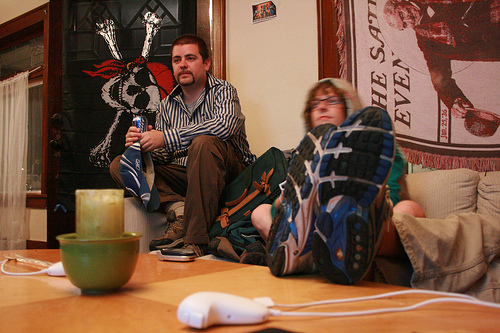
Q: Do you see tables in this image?
A: Yes, there is a table.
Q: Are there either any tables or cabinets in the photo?
A: Yes, there is a table.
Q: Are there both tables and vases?
A: No, there is a table but no vases.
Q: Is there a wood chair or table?
A: Yes, there is a wood table.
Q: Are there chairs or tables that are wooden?
A: Yes, the table is wooden.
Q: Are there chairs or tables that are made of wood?
A: Yes, the table is made of wood.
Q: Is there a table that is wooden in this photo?
A: Yes, there is a wood table.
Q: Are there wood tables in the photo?
A: Yes, there is a wood table.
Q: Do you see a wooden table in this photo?
A: Yes, there is a wood table.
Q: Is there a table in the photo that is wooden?
A: Yes, there is a table that is wooden.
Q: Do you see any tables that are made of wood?
A: Yes, there is a table that is made of wood.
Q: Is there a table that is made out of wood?
A: Yes, there is a table that is made of wood.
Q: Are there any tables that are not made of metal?
A: Yes, there is a table that is made of wood.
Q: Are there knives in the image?
A: No, there are no knives.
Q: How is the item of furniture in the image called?
A: The piece of furniture is a table.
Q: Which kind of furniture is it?
A: The piece of furniture is a table.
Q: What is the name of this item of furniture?
A: This is a table.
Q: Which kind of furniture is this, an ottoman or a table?
A: This is a table.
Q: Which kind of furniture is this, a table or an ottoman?
A: This is a table.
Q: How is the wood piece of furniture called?
A: The piece of furniture is a table.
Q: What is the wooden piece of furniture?
A: The piece of furniture is a table.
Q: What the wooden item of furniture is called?
A: The piece of furniture is a table.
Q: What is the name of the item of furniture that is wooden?
A: The piece of furniture is a table.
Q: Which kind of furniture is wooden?
A: The furniture is a table.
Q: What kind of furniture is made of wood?
A: The furniture is a table.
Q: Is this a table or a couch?
A: This is a table.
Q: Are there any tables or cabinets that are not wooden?
A: No, there is a table but it is wooden.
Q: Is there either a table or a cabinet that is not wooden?
A: No, there is a table but it is wooden.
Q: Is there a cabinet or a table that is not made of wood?
A: No, there is a table but it is made of wood.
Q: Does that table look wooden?
A: Yes, the table is wooden.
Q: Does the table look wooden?
A: Yes, the table is wooden.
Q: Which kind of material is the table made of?
A: The table is made of wood.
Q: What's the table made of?
A: The table is made of wood.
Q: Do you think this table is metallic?
A: No, the table is wooden.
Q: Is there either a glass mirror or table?
A: No, there is a table but it is wooden.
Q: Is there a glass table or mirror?
A: No, there is a table but it is wooden.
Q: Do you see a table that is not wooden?
A: No, there is a table but it is wooden.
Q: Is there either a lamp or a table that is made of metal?
A: No, there is a table but it is made of wood.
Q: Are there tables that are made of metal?
A: No, there is a table but it is made of wood.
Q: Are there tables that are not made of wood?
A: No, there is a table but it is made of wood.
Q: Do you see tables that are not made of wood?
A: No, there is a table but it is made of wood.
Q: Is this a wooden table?
A: Yes, this is a wooden table.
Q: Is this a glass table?
A: No, this is a wooden table.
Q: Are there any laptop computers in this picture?
A: No, there are no laptop computers.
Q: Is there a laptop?
A: No, there are no laptops.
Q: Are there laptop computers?
A: No, there are no laptop computers.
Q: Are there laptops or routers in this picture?
A: No, there are no laptops or routers.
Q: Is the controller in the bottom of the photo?
A: Yes, the controller is in the bottom of the image.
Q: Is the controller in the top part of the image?
A: No, the controller is in the bottom of the image.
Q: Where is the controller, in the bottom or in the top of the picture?
A: The controller is in the bottom of the image.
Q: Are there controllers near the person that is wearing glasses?
A: Yes, there is a controller near the person.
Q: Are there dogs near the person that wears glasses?
A: No, there is a controller near the person.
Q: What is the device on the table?
A: The device is a controller.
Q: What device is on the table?
A: The device is a controller.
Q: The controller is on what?
A: The controller is on the table.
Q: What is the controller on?
A: The controller is on the table.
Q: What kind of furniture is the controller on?
A: The controller is on the table.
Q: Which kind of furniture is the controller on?
A: The controller is on the table.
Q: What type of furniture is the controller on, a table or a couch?
A: The controller is on a table.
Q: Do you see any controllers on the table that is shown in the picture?
A: Yes, there is a controller on the table.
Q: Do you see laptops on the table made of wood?
A: No, there is a controller on the table.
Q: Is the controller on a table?
A: Yes, the controller is on a table.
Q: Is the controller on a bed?
A: No, the controller is on a table.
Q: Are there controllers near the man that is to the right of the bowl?
A: Yes, there is a controller near the man.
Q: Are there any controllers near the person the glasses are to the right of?
A: Yes, there is a controller near the man.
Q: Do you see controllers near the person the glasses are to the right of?
A: Yes, there is a controller near the man.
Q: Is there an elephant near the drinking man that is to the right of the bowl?
A: No, there is a controller near the man.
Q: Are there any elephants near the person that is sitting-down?
A: No, there is a controller near the man.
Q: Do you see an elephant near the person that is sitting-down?
A: No, there is a controller near the man.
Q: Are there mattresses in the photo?
A: No, there are no mattresses.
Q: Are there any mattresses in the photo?
A: No, there are no mattresses.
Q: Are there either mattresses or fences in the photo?
A: No, there are no mattresses or fences.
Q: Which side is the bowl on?
A: The bowl is on the left of the image.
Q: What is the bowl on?
A: The bowl is on the table.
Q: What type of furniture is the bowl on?
A: The bowl is on the table.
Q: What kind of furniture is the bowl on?
A: The bowl is on the table.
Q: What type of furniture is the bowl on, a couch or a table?
A: The bowl is on a table.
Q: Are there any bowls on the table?
A: Yes, there is a bowl on the table.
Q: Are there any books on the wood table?
A: No, there is a bowl on the table.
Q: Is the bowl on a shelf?
A: No, the bowl is on the table.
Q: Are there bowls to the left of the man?
A: Yes, there is a bowl to the left of the man.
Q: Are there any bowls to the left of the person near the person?
A: Yes, there is a bowl to the left of the man.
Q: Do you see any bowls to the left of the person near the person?
A: Yes, there is a bowl to the left of the man.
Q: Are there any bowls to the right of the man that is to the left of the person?
A: No, the bowl is to the left of the man.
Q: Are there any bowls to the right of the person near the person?
A: No, the bowl is to the left of the man.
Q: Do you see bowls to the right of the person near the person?
A: No, the bowl is to the left of the man.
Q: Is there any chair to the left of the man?
A: No, there is a bowl to the left of the man.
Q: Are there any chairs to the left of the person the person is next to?
A: No, there is a bowl to the left of the man.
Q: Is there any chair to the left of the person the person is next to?
A: No, there is a bowl to the left of the man.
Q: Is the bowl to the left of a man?
A: Yes, the bowl is to the left of a man.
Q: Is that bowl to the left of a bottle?
A: No, the bowl is to the left of a man.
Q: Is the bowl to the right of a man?
A: No, the bowl is to the left of a man.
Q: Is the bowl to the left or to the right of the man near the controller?
A: The bowl is to the left of the man.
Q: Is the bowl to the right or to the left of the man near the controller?
A: The bowl is to the left of the man.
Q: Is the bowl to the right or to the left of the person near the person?
A: The bowl is to the left of the man.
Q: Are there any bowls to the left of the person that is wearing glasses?
A: Yes, there is a bowl to the left of the person.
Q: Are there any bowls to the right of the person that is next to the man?
A: No, the bowl is to the left of the person.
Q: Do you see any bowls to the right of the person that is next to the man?
A: No, the bowl is to the left of the person.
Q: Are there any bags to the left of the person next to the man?
A: No, there is a bowl to the left of the person.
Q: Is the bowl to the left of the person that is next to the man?
A: Yes, the bowl is to the left of the person.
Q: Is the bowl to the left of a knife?
A: No, the bowl is to the left of the person.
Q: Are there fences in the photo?
A: No, there are no fences.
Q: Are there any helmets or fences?
A: No, there are no fences or helmets.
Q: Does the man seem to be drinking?
A: Yes, the man is drinking.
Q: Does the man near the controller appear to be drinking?
A: Yes, the man is drinking.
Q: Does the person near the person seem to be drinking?
A: Yes, the man is drinking.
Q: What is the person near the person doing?
A: The man is drinking.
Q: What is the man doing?
A: The man is drinking.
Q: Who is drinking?
A: The man is drinking.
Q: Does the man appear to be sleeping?
A: No, the man is drinking.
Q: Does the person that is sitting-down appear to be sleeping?
A: No, the man is drinking.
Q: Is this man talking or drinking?
A: The man is drinking.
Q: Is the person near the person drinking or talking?
A: The man is drinking.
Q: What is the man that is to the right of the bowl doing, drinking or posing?
A: The man is drinking.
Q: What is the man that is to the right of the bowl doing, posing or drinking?
A: The man is drinking.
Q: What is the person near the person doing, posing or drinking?
A: The man is drinking.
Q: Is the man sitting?
A: Yes, the man is sitting.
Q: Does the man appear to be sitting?
A: Yes, the man is sitting.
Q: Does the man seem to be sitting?
A: Yes, the man is sitting.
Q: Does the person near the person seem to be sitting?
A: Yes, the man is sitting.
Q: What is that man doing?
A: The man is sitting.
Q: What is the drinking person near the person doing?
A: The man is sitting.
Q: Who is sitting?
A: The man is sitting.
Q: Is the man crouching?
A: No, the man is sitting.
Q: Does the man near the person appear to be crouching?
A: No, the man is sitting.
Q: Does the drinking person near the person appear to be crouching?
A: No, the man is sitting.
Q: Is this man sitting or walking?
A: The man is sitting.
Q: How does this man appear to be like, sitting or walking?
A: The man is sitting.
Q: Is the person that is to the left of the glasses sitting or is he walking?
A: The man is sitting.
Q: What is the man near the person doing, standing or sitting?
A: The man is sitting.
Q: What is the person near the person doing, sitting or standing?
A: The man is sitting.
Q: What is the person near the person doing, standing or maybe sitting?
A: The man is sitting.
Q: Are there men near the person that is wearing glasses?
A: Yes, there is a man near the person.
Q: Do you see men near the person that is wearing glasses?
A: Yes, there is a man near the person.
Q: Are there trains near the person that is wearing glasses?
A: No, there is a man near the person.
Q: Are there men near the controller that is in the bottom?
A: Yes, there is a man near the controller.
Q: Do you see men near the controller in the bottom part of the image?
A: Yes, there is a man near the controller.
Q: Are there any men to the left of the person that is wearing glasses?
A: Yes, there is a man to the left of the person.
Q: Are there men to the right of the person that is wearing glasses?
A: No, the man is to the left of the person.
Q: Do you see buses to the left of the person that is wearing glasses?
A: No, there is a man to the left of the person.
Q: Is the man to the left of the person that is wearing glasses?
A: Yes, the man is to the left of the person.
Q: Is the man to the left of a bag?
A: No, the man is to the left of the person.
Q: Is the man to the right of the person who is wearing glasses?
A: No, the man is to the left of the person.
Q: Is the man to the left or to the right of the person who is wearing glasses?
A: The man is to the left of the person.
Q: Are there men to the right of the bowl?
A: Yes, there is a man to the right of the bowl.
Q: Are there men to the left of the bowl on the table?
A: No, the man is to the right of the bowl.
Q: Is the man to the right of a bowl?
A: Yes, the man is to the right of a bowl.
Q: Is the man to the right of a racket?
A: No, the man is to the right of a bowl.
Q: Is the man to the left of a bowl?
A: No, the man is to the right of a bowl.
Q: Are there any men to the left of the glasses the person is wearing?
A: Yes, there is a man to the left of the glasses.